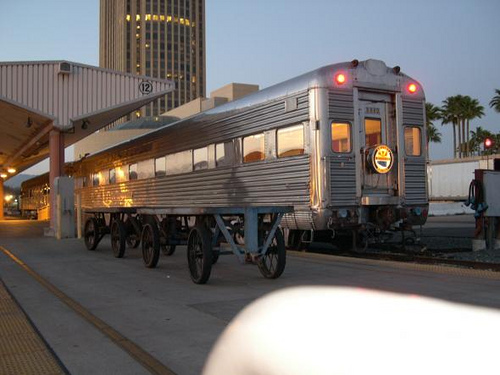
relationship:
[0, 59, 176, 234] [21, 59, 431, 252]
roofing next to train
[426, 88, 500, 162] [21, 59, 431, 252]
trees behind train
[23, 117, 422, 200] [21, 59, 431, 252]
windows on train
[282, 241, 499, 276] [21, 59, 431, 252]
tracks under train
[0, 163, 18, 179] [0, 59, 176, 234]
lights under roofing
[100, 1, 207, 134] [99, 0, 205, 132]
building has windows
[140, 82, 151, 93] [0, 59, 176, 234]
12 on roofing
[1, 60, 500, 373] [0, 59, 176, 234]
train station has roofing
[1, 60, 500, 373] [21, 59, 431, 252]
train station next to train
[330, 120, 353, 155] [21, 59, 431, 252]
window on train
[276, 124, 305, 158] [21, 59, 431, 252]
window on train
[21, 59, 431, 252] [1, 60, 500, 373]
train at train station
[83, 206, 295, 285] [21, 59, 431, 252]
cart next to train